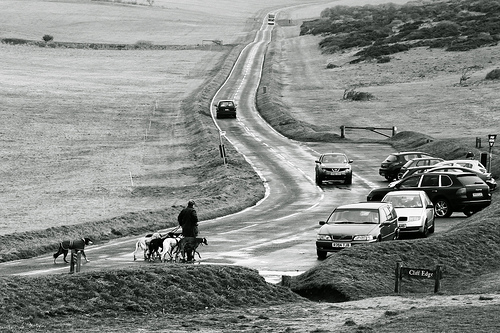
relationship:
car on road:
[313, 151, 356, 186] [244, 130, 289, 165]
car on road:
[212, 97, 237, 120] [1, 20, 401, 292]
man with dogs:
[175, 181, 212, 230] [109, 216, 211, 276]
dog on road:
[174, 236, 208, 262] [84, 39, 381, 269]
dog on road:
[51, 232, 94, 262] [0, 15, 490, 285]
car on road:
[313, 148, 356, 186] [1, 20, 401, 292]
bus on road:
[264, 12, 275, 28] [196, 6, 388, 288]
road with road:
[1, 2, 427, 302] [1, 3, 473, 284]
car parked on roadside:
[314, 203, 399, 260] [249, 48, 459, 303]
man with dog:
[175, 198, 198, 263] [178, 234, 208, 260]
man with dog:
[175, 198, 198, 263] [147, 234, 174, 263]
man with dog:
[175, 198, 198, 263] [134, 230, 163, 265]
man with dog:
[175, 198, 198, 263] [56, 233, 95, 263]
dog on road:
[174, 236, 208, 262] [35, 16, 457, 289]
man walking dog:
[175, 198, 198, 263] [174, 232, 208, 262]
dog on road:
[174, 232, 208, 262] [1, 20, 401, 292]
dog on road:
[174, 236, 208, 262] [1, 20, 401, 292]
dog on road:
[51, 234, 94, 265] [1, 20, 401, 292]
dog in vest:
[174, 236, 208, 262] [71, 237, 87, 254]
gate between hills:
[331, 120, 402, 143] [255, 14, 498, 166]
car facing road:
[354, 166, 497, 234] [1, 20, 401, 292]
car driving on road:
[212, 98, 238, 120] [1, 20, 401, 292]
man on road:
[175, 198, 198, 263] [1, 20, 401, 292]